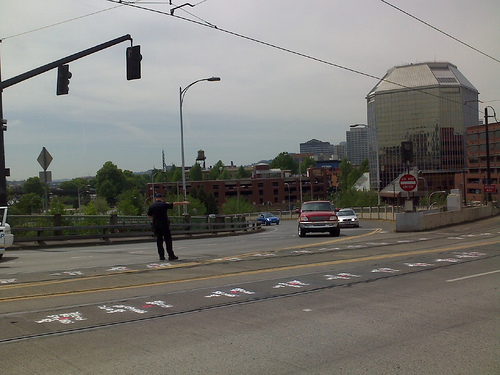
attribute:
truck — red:
[297, 197, 342, 239]